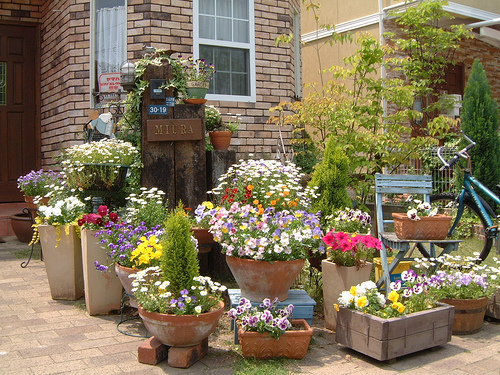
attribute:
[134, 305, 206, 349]
planter — terra cotta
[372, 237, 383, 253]
flower — pink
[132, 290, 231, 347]
pot — terra cotta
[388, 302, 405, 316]
flower — yellow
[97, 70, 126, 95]
sign — red and white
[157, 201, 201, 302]
bush — evergreen 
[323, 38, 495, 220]
bush — tall, green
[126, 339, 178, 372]
brick — red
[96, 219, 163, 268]
flowers — purple, yellow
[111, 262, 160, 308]
planter — round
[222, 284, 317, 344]
stool — blue, wooden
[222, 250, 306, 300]
pot — large, terra cotta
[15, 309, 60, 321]
brick — tan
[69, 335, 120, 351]
brick — tan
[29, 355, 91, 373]
brick — tan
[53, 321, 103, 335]
brick — brown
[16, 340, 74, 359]
brick — brown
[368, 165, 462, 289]
chair — blue, pale blue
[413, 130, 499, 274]
bicycle — blue 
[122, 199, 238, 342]
planter — elevated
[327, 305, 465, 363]
container — wooden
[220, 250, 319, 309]
pot — terracotta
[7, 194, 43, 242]
stand — wrought iron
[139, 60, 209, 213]
display — wooden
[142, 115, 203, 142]
sign — wooden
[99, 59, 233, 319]
planter — tall